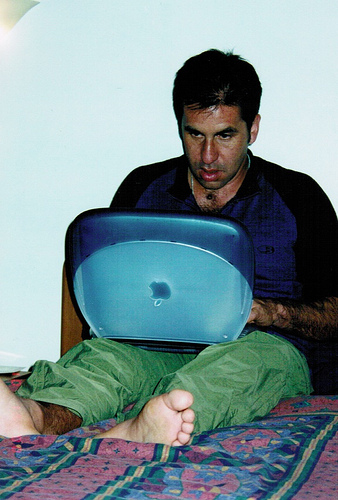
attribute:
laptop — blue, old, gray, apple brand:
[68, 208, 255, 343]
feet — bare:
[0, 375, 196, 448]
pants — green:
[14, 330, 313, 435]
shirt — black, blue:
[107, 147, 337, 355]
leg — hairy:
[30, 394, 83, 436]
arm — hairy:
[250, 293, 337, 342]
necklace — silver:
[187, 148, 251, 192]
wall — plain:
[1, 0, 337, 376]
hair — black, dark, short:
[172, 49, 264, 142]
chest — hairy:
[193, 185, 229, 215]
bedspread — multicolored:
[1, 369, 336, 500]